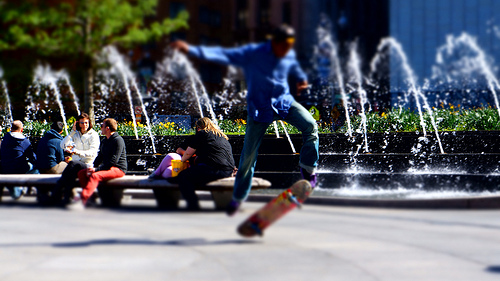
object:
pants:
[232, 101, 320, 201]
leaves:
[0, 0, 191, 56]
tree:
[0, 0, 189, 127]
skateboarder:
[170, 26, 320, 216]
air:
[0, 0, 499, 176]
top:
[93, 132, 128, 174]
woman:
[50, 113, 101, 205]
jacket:
[59, 128, 100, 168]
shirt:
[188, 37, 306, 124]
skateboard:
[236, 180, 313, 238]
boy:
[170, 25, 320, 217]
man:
[65, 118, 126, 211]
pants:
[78, 166, 125, 205]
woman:
[166, 117, 234, 211]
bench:
[0, 173, 271, 212]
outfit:
[179, 130, 235, 206]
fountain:
[25, 61, 81, 135]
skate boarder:
[168, 25, 319, 237]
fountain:
[101, 44, 157, 154]